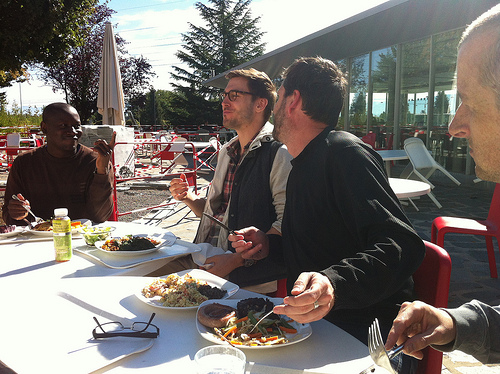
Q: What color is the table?
A: White.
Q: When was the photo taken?
A: Daytime.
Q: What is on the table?
A: Eyeglasses.